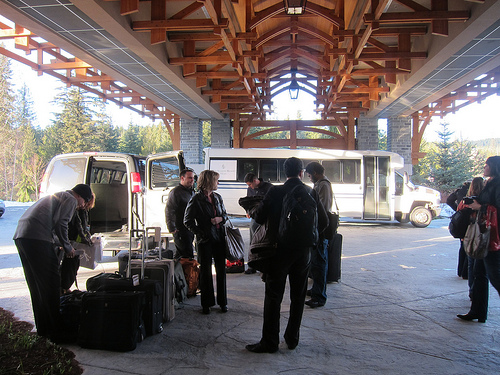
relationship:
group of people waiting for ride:
[238, 157, 330, 353] [202, 147, 443, 227]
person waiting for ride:
[182, 170, 246, 315] [37, 149, 185, 252]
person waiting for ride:
[448, 155, 499, 323] [202, 147, 443, 227]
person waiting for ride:
[11, 182, 93, 342] [37, 149, 185, 252]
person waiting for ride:
[305, 161, 340, 308] [202, 147, 443, 227]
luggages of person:
[59, 226, 201, 352] [11, 182, 93, 342]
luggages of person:
[59, 226, 201, 352] [182, 170, 246, 315]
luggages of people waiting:
[67, 225, 199, 352] [11, 154, 498, 354]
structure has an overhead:
[1, 2, 500, 147] [0, 2, 499, 120]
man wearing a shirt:
[11, 182, 93, 342] [12, 190, 77, 254]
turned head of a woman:
[195, 169, 222, 195] [182, 170, 246, 315]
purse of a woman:
[219, 213, 247, 262] [182, 170, 246, 315]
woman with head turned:
[182, 170, 246, 315] [195, 169, 222, 195]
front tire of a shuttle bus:
[408, 205, 434, 229] [202, 147, 443, 227]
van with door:
[37, 149, 185, 252] [144, 150, 184, 250]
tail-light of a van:
[129, 172, 144, 195] [37, 149, 185, 252]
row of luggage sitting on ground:
[67, 225, 199, 352] [176, 316, 244, 375]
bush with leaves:
[432, 121, 483, 198] [432, 154, 470, 180]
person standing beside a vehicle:
[164, 169, 197, 257] [37, 149, 185, 252]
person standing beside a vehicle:
[241, 171, 273, 196] [37, 149, 185, 252]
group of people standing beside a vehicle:
[11, 156, 340, 353] [37, 149, 185, 252]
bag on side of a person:
[463, 209, 493, 259] [448, 155, 499, 323]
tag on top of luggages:
[131, 272, 140, 289] [59, 226, 201, 352]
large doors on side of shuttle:
[363, 154, 391, 218] [202, 147, 443, 227]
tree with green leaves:
[432, 121, 483, 198] [432, 154, 470, 180]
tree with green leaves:
[14, 129, 42, 203] [16, 178, 36, 202]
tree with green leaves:
[115, 125, 145, 151] [121, 134, 139, 151]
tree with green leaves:
[60, 89, 105, 153] [54, 126, 96, 152]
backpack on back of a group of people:
[278, 183, 320, 250] [238, 157, 330, 353]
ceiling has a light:
[254, 19, 329, 115] [287, 79, 305, 100]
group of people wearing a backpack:
[238, 157, 330, 353] [278, 183, 320, 250]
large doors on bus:
[363, 154, 391, 218] [202, 147, 443, 227]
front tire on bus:
[408, 205, 434, 229] [202, 147, 443, 227]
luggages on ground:
[59, 226, 201, 352] [176, 316, 244, 375]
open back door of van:
[144, 150, 184, 250] [37, 149, 185, 252]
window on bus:
[341, 159, 362, 185] [202, 147, 443, 227]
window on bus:
[323, 160, 343, 182] [202, 147, 443, 227]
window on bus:
[238, 161, 255, 178] [202, 147, 443, 227]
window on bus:
[259, 160, 277, 181] [202, 147, 443, 227]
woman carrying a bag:
[182, 170, 246, 315] [219, 213, 247, 262]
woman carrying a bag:
[448, 155, 499, 323] [462, 207, 493, 261]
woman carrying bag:
[448, 155, 499, 323] [463, 209, 493, 259]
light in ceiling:
[287, 79, 305, 100] [254, 19, 329, 115]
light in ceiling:
[284, 0, 307, 18] [254, 19, 329, 115]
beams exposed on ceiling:
[131, 4, 472, 119] [254, 19, 329, 115]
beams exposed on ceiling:
[119, 0, 484, 122] [254, 19, 329, 115]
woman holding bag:
[182, 170, 246, 315] [219, 213, 247, 262]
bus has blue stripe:
[202, 147, 443, 227] [217, 186, 247, 190]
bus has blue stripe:
[202, 147, 443, 227] [219, 183, 248, 187]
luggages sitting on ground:
[59, 226, 201, 352] [176, 316, 244, 375]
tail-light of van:
[129, 172, 144, 195] [37, 149, 185, 252]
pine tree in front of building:
[428, 121, 474, 198] [1, 2, 500, 147]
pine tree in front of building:
[14, 129, 42, 203] [1, 2, 500, 147]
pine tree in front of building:
[60, 89, 105, 153] [1, 2, 500, 147]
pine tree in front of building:
[115, 125, 145, 151] [1, 2, 500, 147]